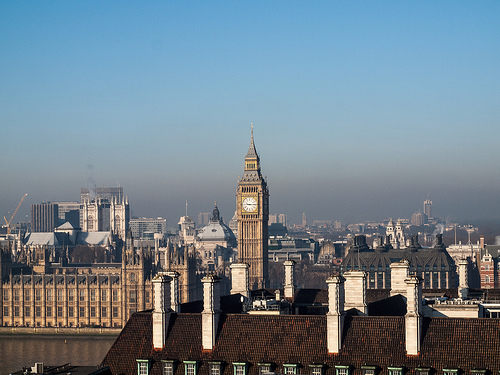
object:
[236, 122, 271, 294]
big ben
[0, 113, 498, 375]
london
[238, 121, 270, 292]
clock tower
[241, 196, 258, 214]
clock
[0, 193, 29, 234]
construction crane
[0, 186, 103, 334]
building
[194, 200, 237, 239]
dome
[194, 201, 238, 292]
church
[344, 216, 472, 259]
building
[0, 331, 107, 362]
river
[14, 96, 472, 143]
sky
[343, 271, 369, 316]
chimney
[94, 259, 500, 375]
building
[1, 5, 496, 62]
sky